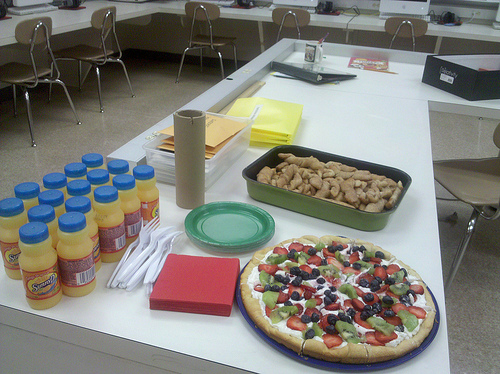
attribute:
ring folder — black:
[276, 58, 358, 88]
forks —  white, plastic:
[105, 218, 186, 294]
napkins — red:
[145, 250, 241, 317]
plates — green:
[185, 197, 275, 250]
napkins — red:
[152, 255, 237, 312]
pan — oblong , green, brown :
[250, 143, 401, 229]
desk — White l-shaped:
[161, 37, 473, 349]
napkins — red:
[155, 252, 242, 313]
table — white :
[3, 48, 444, 372]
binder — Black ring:
[268, 57, 360, 88]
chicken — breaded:
[314, 170, 401, 205]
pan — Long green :
[241, 142, 411, 232]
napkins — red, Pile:
[156, 244, 231, 350]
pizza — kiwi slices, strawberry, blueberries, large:
[238, 235, 436, 362]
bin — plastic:
[139, 108, 254, 193]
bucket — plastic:
[145, 111, 250, 186]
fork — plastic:
[136, 218, 153, 241]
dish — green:
[240, 138, 415, 229]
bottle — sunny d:
[52, 208, 97, 298]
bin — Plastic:
[146, 104, 251, 186]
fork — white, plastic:
[158, 230, 185, 287]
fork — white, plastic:
[113, 215, 160, 291]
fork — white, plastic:
[123, 223, 174, 289]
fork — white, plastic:
[105, 215, 144, 288]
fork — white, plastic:
[116, 222, 173, 292]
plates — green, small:
[180, 195, 279, 251]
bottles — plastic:
[4, 153, 154, 310]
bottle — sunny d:
[93, 185, 126, 262]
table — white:
[1, 34, 498, 372]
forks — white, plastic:
[106, 215, 184, 291]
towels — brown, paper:
[159, 109, 230, 229]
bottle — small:
[18, 222, 67, 314]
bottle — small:
[57, 204, 98, 294]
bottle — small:
[93, 183, 131, 263]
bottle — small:
[111, 172, 142, 241]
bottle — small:
[129, 163, 160, 227]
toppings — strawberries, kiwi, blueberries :
[277, 249, 409, 336]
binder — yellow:
[233, 85, 309, 144]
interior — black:
[267, 159, 273, 166]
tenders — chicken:
[277, 163, 324, 188]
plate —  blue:
[242, 301, 253, 324]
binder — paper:
[272, 53, 360, 93]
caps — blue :
[59, 211, 85, 231]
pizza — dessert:
[256, 234, 439, 364]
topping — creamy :
[250, 272, 257, 280]